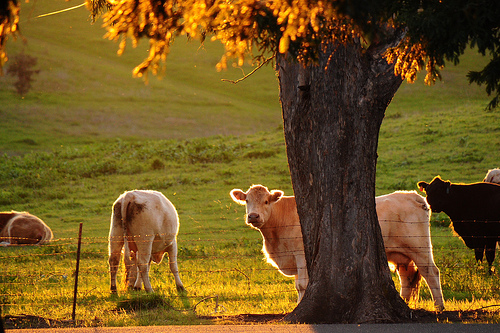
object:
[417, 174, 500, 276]
cow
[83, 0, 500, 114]
leaves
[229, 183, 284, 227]
cow's face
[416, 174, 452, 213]
cow's face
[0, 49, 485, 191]
ground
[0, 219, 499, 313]
wire fence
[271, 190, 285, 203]
ear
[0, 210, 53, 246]
cow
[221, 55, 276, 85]
branch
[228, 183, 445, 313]
beige cow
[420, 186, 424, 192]
tag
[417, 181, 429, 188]
ear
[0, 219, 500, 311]
wire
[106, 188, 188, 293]
cow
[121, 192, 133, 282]
tail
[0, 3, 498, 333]
grass field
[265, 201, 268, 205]
eye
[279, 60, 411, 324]
bark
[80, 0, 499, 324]
tree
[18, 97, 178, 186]
field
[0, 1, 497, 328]
grass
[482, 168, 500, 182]
cow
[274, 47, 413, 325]
trunk